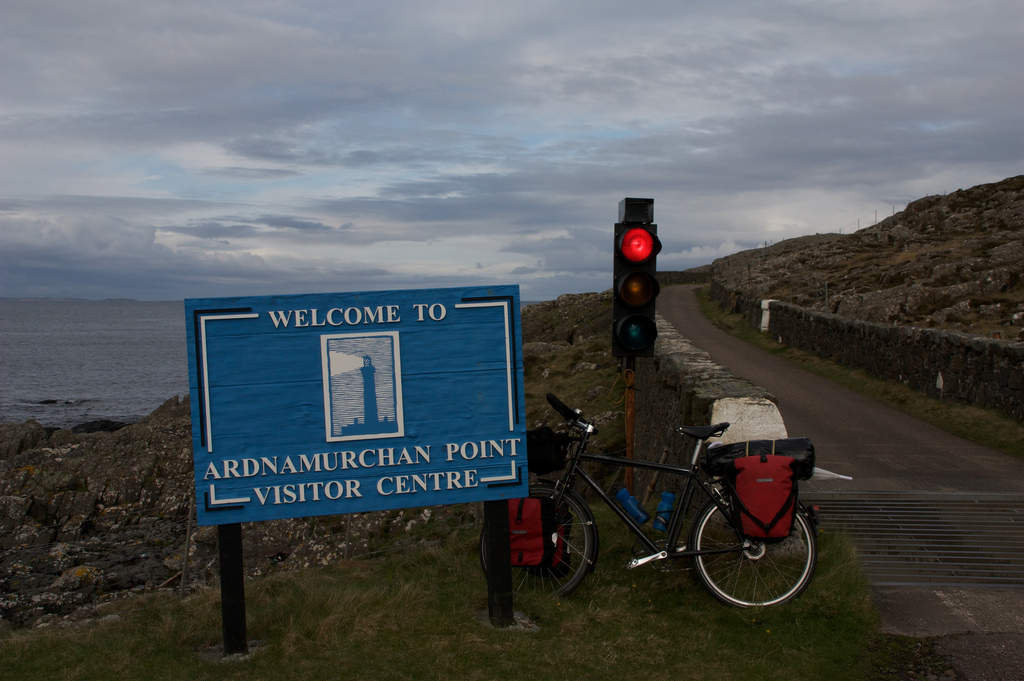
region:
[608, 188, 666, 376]
traffic light is shining red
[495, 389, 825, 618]
bike is parked on the side of the road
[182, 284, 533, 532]
blue, white, and black sign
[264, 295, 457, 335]
white writing on a blue background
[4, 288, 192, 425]
a body of water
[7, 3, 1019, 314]
sky is covered in clouds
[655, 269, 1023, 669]
a very narrow road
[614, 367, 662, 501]
pole supporting the traffic light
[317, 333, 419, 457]
picture on the sign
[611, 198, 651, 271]
red signal light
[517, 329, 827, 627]
bike parked near road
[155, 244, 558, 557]
large blue and white sign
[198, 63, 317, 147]
white clouds in blue sky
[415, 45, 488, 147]
white clouds in blue sky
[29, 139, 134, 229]
white clouds in blue sky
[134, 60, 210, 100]
white clouds in blue sky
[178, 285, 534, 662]
welcome sign secured into the ground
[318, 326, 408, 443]
lighthouse picture on a sign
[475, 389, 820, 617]
bicycle propped up against a rock wall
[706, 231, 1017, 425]
rock wall along a path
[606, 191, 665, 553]
stoplight is red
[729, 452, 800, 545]
red bag attached to a bicycle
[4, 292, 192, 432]
large body of water beyond a rocky coast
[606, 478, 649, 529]
water bottle on the frame of the bicycle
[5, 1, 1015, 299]
cloudy dark sky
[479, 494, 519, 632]
black metal support beam on a sign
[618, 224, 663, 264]
the light is red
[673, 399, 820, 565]
the bike is leaning on the barrier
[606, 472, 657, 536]
the bottle is blue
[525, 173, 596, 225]
the clouds are gray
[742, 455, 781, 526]
the bag is red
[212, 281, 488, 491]
the sign is blue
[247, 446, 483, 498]
the sign has white letters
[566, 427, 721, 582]
the bike is black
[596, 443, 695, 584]
the bottles are attached to the bike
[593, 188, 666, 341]
red colored signal light by road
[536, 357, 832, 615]
bike parked near sign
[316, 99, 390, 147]
white clouds in blue sky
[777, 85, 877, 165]
white clouds in blue sky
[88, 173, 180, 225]
white clouds in blue sky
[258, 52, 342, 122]
white clouds in blue sky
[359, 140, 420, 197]
white clouds in blue sky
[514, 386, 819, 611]
a parked black bicycle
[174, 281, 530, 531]
a blue welcome sign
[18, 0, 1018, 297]
a cloudy grey sky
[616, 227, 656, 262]
a red stop light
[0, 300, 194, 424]
a body of water in distance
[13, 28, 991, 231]
clouds in the sky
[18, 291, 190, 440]
a large body of water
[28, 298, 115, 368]
waves in the water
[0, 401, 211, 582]
large black rocks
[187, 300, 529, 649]
a blue sign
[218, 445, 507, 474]
writing on the sign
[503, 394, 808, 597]
a black bicycle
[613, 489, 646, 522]
a blue water bottle on the bicycle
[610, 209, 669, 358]
a red street light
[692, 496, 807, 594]
the tire on the bicycle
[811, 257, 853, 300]
rock on the side of the road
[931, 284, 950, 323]
rock on the side of the road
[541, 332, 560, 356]
rock on the side of the road